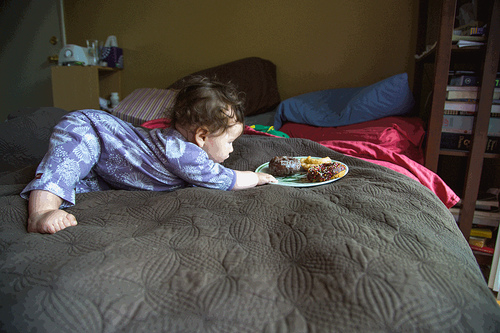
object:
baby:
[26, 74, 276, 235]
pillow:
[272, 71, 420, 130]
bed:
[0, 58, 500, 330]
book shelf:
[413, 0, 498, 255]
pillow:
[110, 87, 182, 129]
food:
[302, 154, 344, 182]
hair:
[167, 72, 247, 136]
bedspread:
[0, 135, 499, 330]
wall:
[282, 15, 394, 90]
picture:
[1, 0, 498, 332]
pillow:
[167, 55, 280, 117]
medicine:
[110, 90, 119, 107]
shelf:
[52, 60, 119, 112]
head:
[172, 76, 246, 163]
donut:
[269, 155, 304, 176]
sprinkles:
[320, 161, 346, 170]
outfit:
[18, 108, 237, 208]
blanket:
[0, 110, 499, 332]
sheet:
[140, 118, 461, 208]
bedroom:
[4, 4, 497, 331]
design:
[2, 132, 454, 328]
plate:
[254, 152, 349, 188]